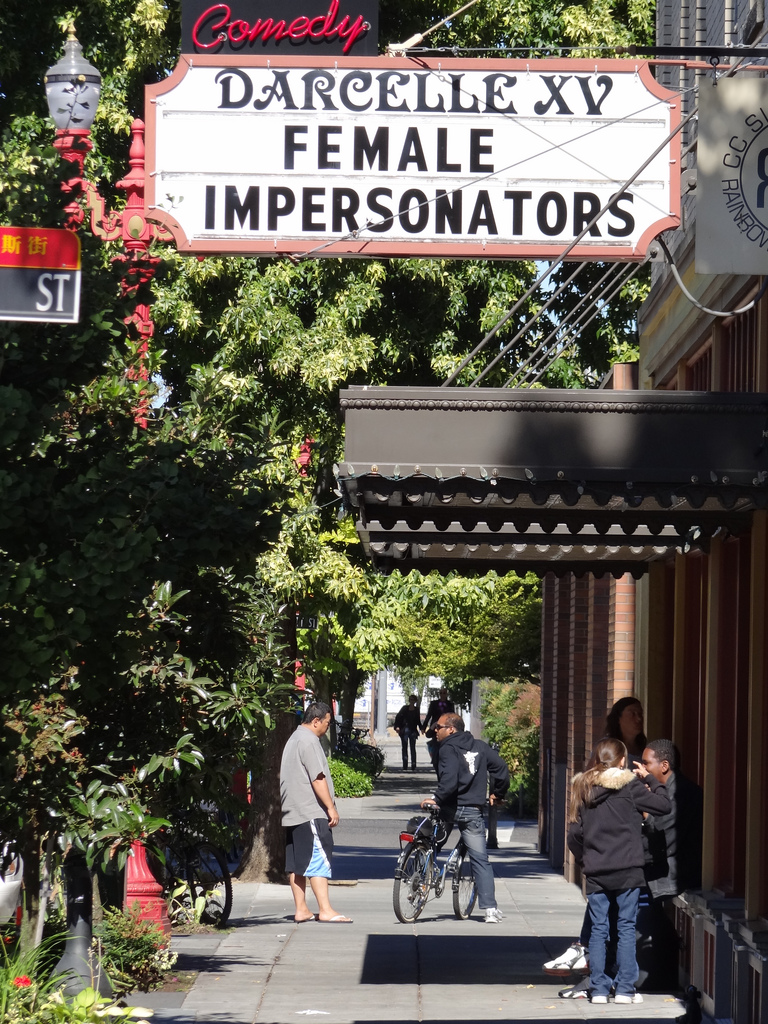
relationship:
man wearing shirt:
[278, 700, 348, 921] [281, 724, 338, 826]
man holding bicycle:
[430, 713, 508, 920] [394, 797, 485, 918]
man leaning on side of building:
[544, 738, 682, 971] [543, 0, 764, 1022]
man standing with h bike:
[430, 713, 508, 920] [393, 806, 478, 921]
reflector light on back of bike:
[397, 832, 412, 841] [391, 800, 482, 920]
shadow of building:
[361, 931, 666, 986] [543, 0, 764, 1022]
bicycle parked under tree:
[160, 817, 232, 924] [0, 1, 657, 1016]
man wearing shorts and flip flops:
[278, 700, 348, 921] [299, 887, 361, 980]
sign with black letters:
[134, 57, 725, 276] [320, 524, 667, 623]